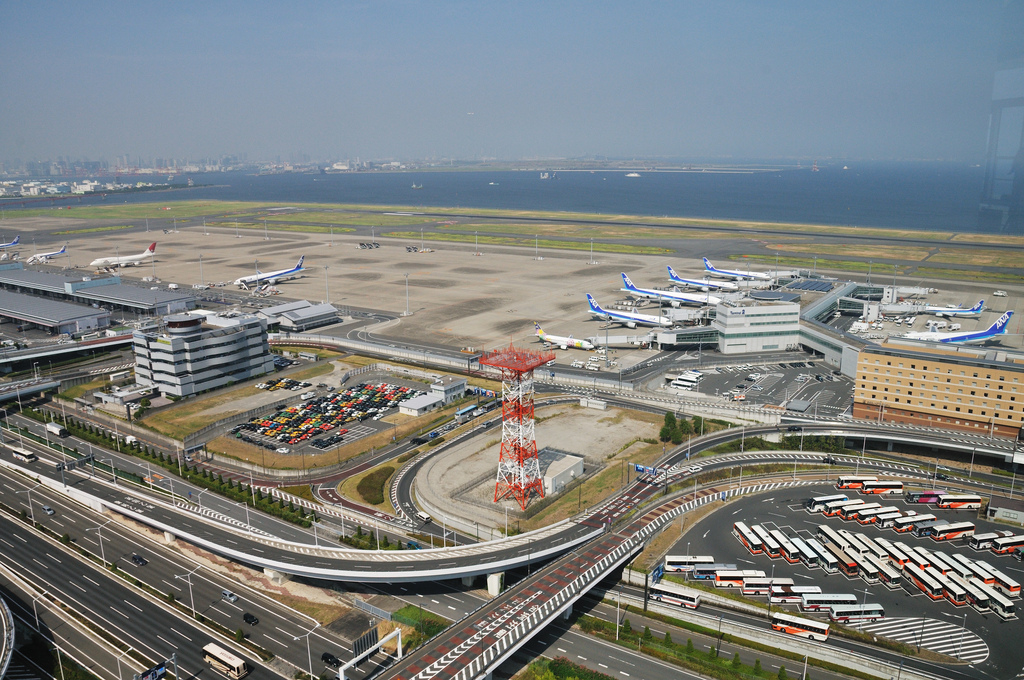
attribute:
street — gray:
[364, 478, 840, 677]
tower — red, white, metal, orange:
[472, 342, 557, 513]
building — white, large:
[128, 301, 278, 407]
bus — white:
[727, 517, 764, 552]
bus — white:
[752, 521, 785, 560]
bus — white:
[787, 534, 822, 573]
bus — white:
[804, 536, 839, 573]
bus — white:
[923, 564, 971, 610]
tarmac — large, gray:
[11, 221, 789, 373]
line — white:
[154, 631, 181, 649]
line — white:
[169, 623, 193, 641]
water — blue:
[3, 160, 993, 234]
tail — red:
[145, 238, 159, 252]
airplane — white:
[83, 236, 163, 269]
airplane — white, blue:
[580, 288, 674, 330]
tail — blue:
[580, 290, 602, 316]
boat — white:
[621, 169, 643, 178]